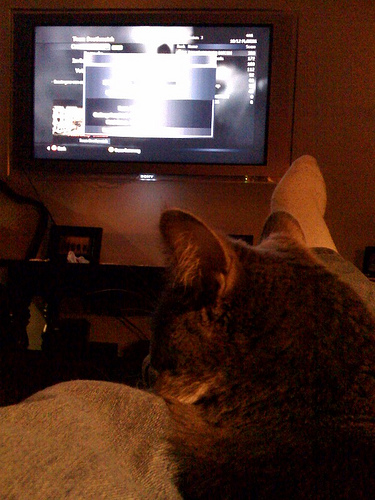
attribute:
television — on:
[16, 16, 297, 180]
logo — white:
[138, 172, 157, 178]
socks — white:
[245, 141, 349, 255]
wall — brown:
[312, 84, 368, 148]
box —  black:
[78, 47, 216, 137]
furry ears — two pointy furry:
[132, 200, 335, 305]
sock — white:
[272, 154, 335, 249]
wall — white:
[0, 0, 366, 364]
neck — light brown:
[204, 343, 268, 406]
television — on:
[18, 18, 281, 185]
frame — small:
[47, 221, 105, 263]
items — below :
[67, 321, 143, 369]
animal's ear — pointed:
[158, 210, 230, 295]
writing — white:
[57, 116, 152, 171]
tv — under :
[40, 23, 241, 139]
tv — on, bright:
[6, 4, 299, 191]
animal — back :
[146, 203, 373, 498]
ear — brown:
[255, 209, 313, 256]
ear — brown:
[156, 200, 244, 307]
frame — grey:
[15, 9, 303, 180]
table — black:
[46, 184, 192, 357]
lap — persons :
[7, 362, 196, 482]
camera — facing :
[161, 315, 325, 459]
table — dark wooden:
[38, 223, 200, 361]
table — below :
[22, 234, 216, 379]